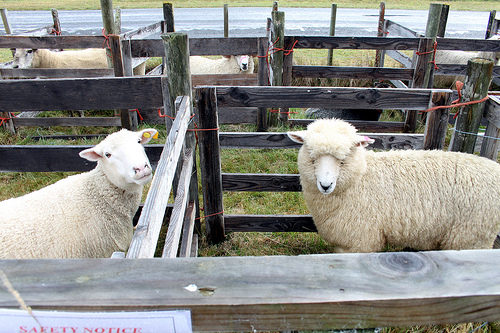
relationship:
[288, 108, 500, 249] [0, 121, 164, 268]
sheep with sheep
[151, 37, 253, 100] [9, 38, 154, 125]
sheep with sheep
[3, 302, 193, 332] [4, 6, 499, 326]
sign on fence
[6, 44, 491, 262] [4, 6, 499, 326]
grass growing around fence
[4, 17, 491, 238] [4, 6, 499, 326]
string on fence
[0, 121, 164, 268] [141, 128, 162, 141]
sheep has tag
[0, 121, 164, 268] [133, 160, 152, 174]
sheep has nose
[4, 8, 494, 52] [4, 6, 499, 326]
water behind fence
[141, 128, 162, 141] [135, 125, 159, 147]
tag on ear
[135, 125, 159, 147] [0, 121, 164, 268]
ear of sheep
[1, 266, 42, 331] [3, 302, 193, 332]
twine attached to sign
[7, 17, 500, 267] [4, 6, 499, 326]
sheep surrounded by fence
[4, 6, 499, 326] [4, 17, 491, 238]
fence secured with string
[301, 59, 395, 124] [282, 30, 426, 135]
sheep behind gate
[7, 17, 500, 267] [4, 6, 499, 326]
sheep in fence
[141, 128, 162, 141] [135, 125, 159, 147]
tag in ear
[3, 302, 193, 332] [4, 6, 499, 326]
sign attached to fence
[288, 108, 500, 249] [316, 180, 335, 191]
sheep with nose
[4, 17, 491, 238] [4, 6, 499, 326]
string around fence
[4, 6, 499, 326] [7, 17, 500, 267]
fence around sheep